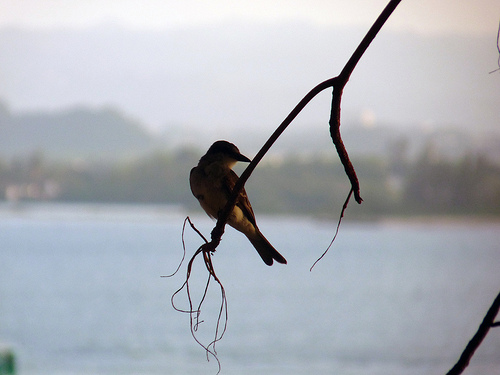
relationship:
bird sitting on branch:
[190, 139, 288, 267] [159, 1, 402, 375]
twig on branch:
[161, 217, 209, 277] [159, 1, 402, 375]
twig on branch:
[172, 244, 202, 315] [159, 1, 402, 375]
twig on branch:
[193, 251, 212, 331] [159, 1, 402, 375]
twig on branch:
[207, 291, 229, 363] [159, 1, 402, 375]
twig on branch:
[186, 244, 221, 375] [159, 1, 402, 375]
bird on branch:
[190, 139, 288, 267] [159, 1, 402, 375]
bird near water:
[190, 139, 288, 267] [0, 202, 499, 375]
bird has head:
[190, 139, 288, 267] [198, 139, 253, 168]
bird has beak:
[190, 139, 288, 267] [236, 153, 250, 163]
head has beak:
[198, 139, 253, 168] [236, 153, 250, 163]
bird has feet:
[190, 139, 288, 267] [215, 209, 232, 224]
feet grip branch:
[215, 209, 232, 224] [159, 1, 402, 375]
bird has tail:
[190, 139, 288, 267] [242, 223, 289, 267]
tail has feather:
[242, 223, 289, 267] [256, 225, 288, 265]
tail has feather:
[242, 223, 289, 267] [248, 235, 275, 267]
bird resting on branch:
[190, 139, 288, 267] [159, 1, 402, 375]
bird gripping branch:
[190, 139, 288, 267] [159, 1, 402, 375]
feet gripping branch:
[215, 209, 232, 224] [159, 1, 402, 375]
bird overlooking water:
[190, 139, 288, 267] [0, 202, 499, 375]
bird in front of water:
[190, 139, 288, 267] [0, 202, 499, 375]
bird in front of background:
[190, 139, 288, 267] [2, 0, 499, 374]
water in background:
[0, 202, 499, 375] [2, 0, 499, 374]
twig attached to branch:
[160, 77, 332, 375] [159, 1, 402, 375]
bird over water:
[190, 139, 288, 267] [0, 202, 499, 375]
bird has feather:
[190, 139, 288, 267] [256, 225, 288, 265]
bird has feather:
[190, 139, 288, 267] [248, 235, 275, 267]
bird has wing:
[190, 139, 288, 267] [224, 170, 258, 226]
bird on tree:
[190, 139, 288, 267] [161, 1, 499, 375]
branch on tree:
[159, 1, 402, 375] [161, 1, 499, 375]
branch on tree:
[445, 294, 500, 374] [161, 1, 499, 375]